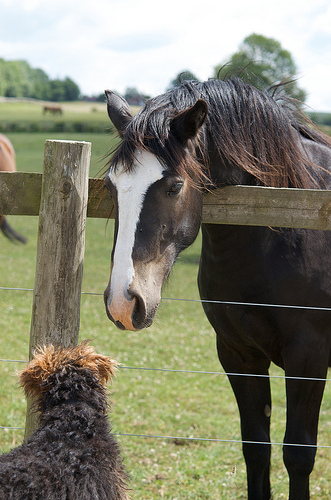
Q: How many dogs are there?
A: One.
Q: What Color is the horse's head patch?
A: White.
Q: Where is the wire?
A: On the fence.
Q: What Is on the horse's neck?
A: Mane.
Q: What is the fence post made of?
A: Wood.